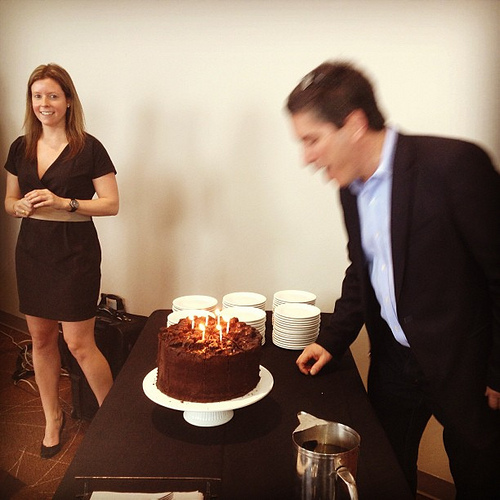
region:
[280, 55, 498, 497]
Man about to blow out candles on a cake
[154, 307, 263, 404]
Chocolate cakes with candles lit on it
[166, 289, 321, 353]
Six stacks of small white plates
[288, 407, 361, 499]
Silver water pitcher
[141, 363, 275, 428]
White decorative ceramic cake stand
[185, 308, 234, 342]
Six lit candles on a cake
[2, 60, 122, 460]
Woman in a black dress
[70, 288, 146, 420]
Suitcase sitting next to a wall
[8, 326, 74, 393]
Several jumbled cords on the ground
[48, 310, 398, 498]
Dark wood table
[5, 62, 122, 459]
a woman in a cocktail dress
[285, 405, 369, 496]
a metal water pitcher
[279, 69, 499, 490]
a professionally dressed man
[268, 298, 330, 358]
a stack of white plates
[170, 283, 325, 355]
rows of desert plates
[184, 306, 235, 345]
a few lit birthday candles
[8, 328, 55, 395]
a pile of power cords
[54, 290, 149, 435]
a piece of black luggage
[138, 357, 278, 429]
a white serving dish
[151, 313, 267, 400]
a tall chocolate cake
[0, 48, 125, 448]
lady wearing black dress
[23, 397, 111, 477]
lady wearing black heels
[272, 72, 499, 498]
man wearing black jacket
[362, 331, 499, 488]
man wearing black pants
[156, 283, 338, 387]
white plate stacked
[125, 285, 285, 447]
chocolate cake on cake platter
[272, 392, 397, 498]
silver jug on table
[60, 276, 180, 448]
black suit case on floor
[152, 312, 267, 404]
A round chocolate cake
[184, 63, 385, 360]
Man is about to blow out the candles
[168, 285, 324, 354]
Stacks of small white plates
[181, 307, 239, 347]
Lit candles on top of the cake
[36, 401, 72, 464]
A black high heel shoe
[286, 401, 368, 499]
The pitcher is silver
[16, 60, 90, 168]
Lady has long brown hair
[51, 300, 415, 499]
The table is black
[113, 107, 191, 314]
Lady's shadow on the wall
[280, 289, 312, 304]
stack of plates on table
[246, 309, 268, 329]
stack of plates on table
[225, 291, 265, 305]
stack of plates on table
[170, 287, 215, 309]
stack of plates on table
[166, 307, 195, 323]
stack of plates on table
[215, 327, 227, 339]
candle on the cake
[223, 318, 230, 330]
candle on the cake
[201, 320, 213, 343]
candle on the cake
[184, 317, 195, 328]
candle on the cake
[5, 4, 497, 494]
Interior with birthday cake and people.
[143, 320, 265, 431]
Chocolate cake with sprinkles and candles on white cake dish.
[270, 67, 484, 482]
Blurry, Caucasian man in suit, blowing candles.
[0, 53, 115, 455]
Smiling, standing woman, in black dress and pumps.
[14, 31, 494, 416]
a scene at a diner room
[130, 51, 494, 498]
a man blowing at cakes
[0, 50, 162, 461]
a woman looking at the cake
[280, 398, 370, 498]
a silver pitcher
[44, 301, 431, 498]
a black table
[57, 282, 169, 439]
a black suitcase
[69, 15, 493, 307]
a white wall in the background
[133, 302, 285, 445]
a chocolate cake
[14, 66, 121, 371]
woman whit a black dress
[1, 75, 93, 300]
woman with long blond hair